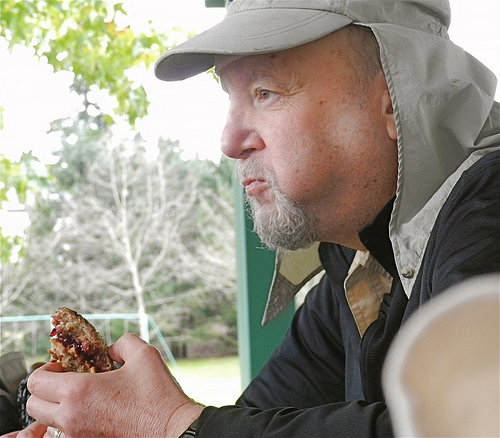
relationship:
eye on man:
[244, 80, 283, 124] [3, 2, 497, 434]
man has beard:
[3, 2, 497, 434] [237, 163, 331, 258]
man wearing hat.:
[3, 2, 497, 434] [149, 2, 495, 257]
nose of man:
[222, 99, 264, 157] [3, 2, 497, 434]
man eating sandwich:
[3, 2, 497, 434] [48, 300, 115, 375]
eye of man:
[253, 86, 284, 104] [3, 2, 497, 434]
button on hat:
[396, 260, 411, 277] [150, 0, 474, 275]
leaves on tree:
[31, 0, 121, 90] [55, 154, 220, 332]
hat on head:
[152, 2, 497, 102] [137, 5, 477, 265]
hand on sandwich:
[21, 342, 187, 435] [32, 293, 127, 387]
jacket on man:
[190, 149, 498, 436] [3, 2, 497, 434]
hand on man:
[21, 329, 205, 435] [3, 2, 497, 434]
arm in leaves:
[15, 327, 394, 434] [0, 0, 180, 127]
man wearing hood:
[1, 0, 495, 438] [140, 1, 497, 227]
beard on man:
[235, 190, 328, 259] [3, 2, 497, 434]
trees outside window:
[0, 4, 236, 354] [1, 0, 239, 407]